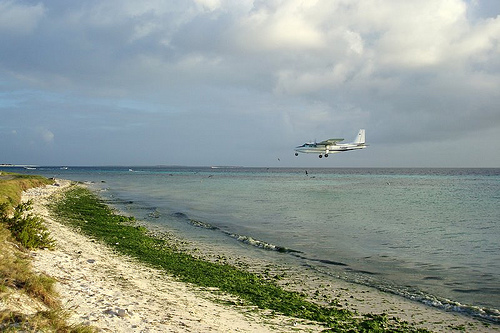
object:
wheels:
[317, 152, 323, 158]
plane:
[293, 128, 370, 160]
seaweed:
[49, 187, 425, 331]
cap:
[246, 236, 259, 243]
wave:
[228, 232, 295, 258]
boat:
[209, 166, 222, 171]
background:
[1, 0, 499, 332]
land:
[0, 173, 440, 332]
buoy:
[384, 180, 390, 187]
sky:
[3, 0, 498, 168]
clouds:
[0, 1, 500, 166]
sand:
[23, 175, 500, 332]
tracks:
[45, 240, 192, 333]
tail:
[355, 128, 365, 146]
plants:
[6, 199, 60, 250]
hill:
[0, 168, 195, 332]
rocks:
[324, 282, 336, 290]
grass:
[0, 171, 91, 333]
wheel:
[296, 152, 299, 157]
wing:
[323, 138, 344, 146]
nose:
[294, 145, 300, 154]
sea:
[1, 163, 499, 325]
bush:
[0, 198, 52, 249]